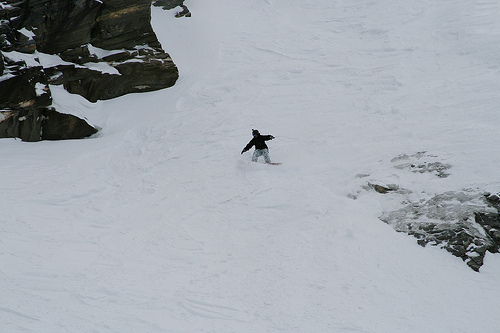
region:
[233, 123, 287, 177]
a person on a snow board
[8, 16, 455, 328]
the mountain side is covered in snow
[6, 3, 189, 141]
big rocks are to the left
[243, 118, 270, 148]
the person is wearing a dark jacket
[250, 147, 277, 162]
their pants are a light color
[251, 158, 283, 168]
a small portion of the snow board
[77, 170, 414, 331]
the snow is white in color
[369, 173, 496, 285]
more rocks are to the right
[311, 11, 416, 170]
a trail can be seen behind the snow boarder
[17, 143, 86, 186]
the snow has not been disturbed in this area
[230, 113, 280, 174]
person on a snow board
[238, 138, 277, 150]
man with a black jacket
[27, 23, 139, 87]
snow on a mountain top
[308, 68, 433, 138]
snow on the ground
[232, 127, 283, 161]
person with their arms open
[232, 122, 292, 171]
person in the snow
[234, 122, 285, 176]
person on a snowboard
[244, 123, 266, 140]
person wearing a hat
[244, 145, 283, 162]
person wearing blue jeans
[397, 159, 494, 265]
ice on the mountain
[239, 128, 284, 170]
Person snowboarding in the snow.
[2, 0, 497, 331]
Snow covering the ground.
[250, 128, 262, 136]
black hat on the person.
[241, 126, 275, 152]
black jacket on the person.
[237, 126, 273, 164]
White snow pants on the person.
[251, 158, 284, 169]
Snowboard in the snow.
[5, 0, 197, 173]
Part of a mountain in the background.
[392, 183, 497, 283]
Gray rock in the snow.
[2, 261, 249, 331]
Tracks in the snow.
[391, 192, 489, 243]
Snow and ice on the rock.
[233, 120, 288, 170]
man in the snow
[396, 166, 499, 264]
ice on a rock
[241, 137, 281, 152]
person wearing a black jacket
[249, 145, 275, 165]
person wearing white pants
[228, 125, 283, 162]
man with his arms over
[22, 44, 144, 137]
snow on a mountain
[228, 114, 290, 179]
person standing in the snow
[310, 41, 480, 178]
snow on the ground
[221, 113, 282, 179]
person snow boarding on a mountain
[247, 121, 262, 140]
person wearing a black hair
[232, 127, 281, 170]
a person in the snow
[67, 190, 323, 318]
the snow is white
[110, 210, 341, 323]
the snow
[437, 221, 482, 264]
a rock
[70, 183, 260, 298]
the white snow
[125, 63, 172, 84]
the rock is brown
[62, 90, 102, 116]
snow on the rock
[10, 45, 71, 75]
the rock has snow on it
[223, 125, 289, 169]
a person in the white snow